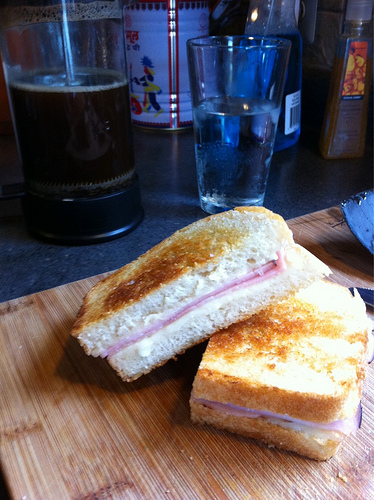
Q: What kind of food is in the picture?
A: Sandwich.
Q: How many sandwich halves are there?
A: Two.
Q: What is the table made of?
A: Wood.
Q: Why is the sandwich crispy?
A: It was toasted.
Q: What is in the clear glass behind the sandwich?
A: Water.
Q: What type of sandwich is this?
A: Ham.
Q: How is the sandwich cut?
A: In half.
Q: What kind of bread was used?
A: White.